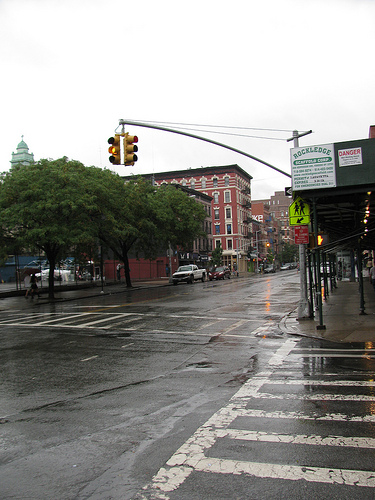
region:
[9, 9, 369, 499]
It is rainy outside.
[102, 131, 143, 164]
The street light is yellow.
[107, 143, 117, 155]
The light is yellow.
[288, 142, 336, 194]
The sign is white.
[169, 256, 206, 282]
The truck is white.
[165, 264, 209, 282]
The truck is parked.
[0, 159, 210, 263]
The trees are leafy.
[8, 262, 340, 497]
The street is wet.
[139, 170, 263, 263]
The building is brick.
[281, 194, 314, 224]
The sign is yellow.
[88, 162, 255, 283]
Large red building with white frames around windows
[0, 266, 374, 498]
Wet looking road with painted white lines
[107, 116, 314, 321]
Set of traffic lights fixed to an overhanging post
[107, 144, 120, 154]
Yellow light lit up in set of trafffic lights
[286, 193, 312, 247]
Yellow and red traffic signs affixed to post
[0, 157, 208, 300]
Two large bushy trees on the sidewalk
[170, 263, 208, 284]
White car parked by the side of the street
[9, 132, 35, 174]
Grey old-looking tower behind trees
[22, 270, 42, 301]
Couple walking on the sidewalk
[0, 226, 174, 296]
Tall wire fence next to the sidewalk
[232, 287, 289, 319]
water on the street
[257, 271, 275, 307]
orange light reflecting on the street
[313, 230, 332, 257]
yellow sign on the traffic sign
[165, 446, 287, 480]
broken white lines on the street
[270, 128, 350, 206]
green and white sign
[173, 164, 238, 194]
decorative white design on building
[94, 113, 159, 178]
yellow street traffic sign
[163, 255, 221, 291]
white car parked on side of the road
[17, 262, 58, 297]
people walking on the sidewalk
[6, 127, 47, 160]
green dome of tall building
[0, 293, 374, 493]
"The roads are wet"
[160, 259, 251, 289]
"The cars are parked"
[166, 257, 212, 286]
"This truck is white"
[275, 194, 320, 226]
"The sign is yellow and black"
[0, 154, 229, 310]
"Two trees are pictured here"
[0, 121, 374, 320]
"Buildings are pictured here"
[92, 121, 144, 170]
"A street light"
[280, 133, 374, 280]
"Several signs can be seen"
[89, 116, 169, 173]
"The street light is yellow"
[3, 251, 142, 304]
"People are walking on the sidewalk"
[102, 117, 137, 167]
Yellow stoplight with a yellow signal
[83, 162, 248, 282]
Red brick apartment building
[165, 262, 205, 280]
White truck parked on the side of the road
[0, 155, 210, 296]
Two large green trees.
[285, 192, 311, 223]
Yellow crosswalk sign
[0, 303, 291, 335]
White street crosswalk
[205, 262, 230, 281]
Red car parked on the side of the road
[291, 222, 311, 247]
Red street sign on a pole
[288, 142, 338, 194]
White sign with green lettering.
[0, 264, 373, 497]
Black asphalt wet from rain